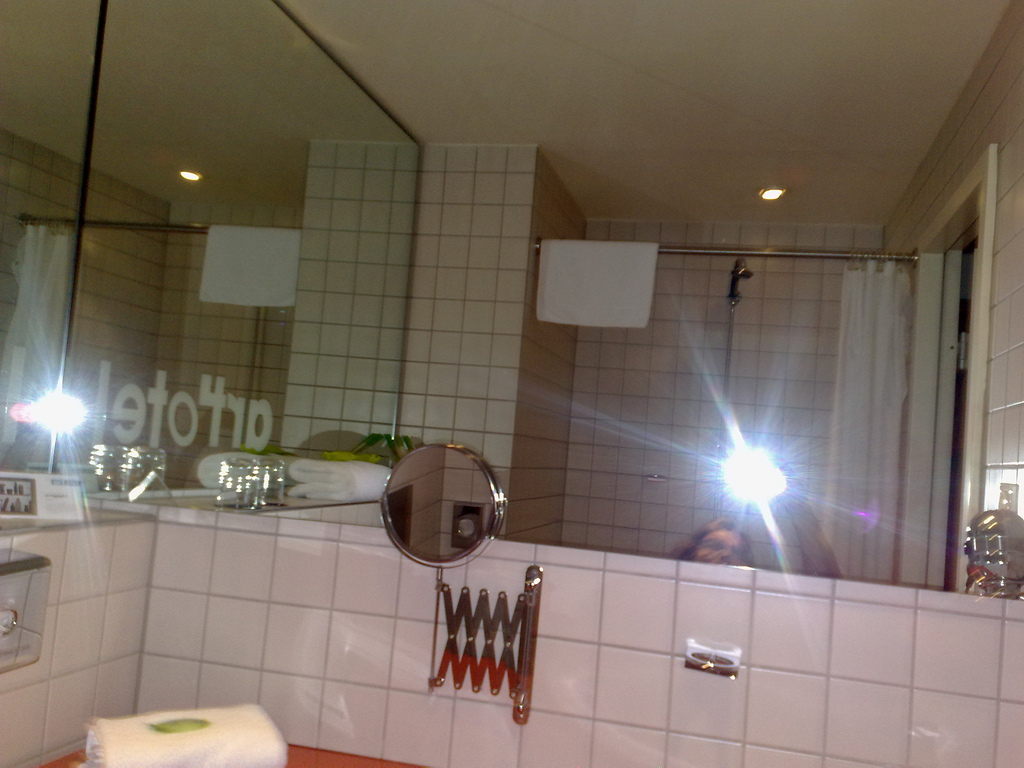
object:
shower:
[719, 259, 746, 305]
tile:
[247, 578, 344, 678]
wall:
[172, 519, 393, 738]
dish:
[678, 634, 748, 680]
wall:
[573, 553, 861, 764]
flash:
[557, 269, 908, 581]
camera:
[714, 430, 790, 510]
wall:
[154, 510, 852, 760]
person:
[675, 492, 844, 583]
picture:
[9, 7, 1017, 761]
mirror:
[56, 2, 420, 489]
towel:
[534, 234, 655, 329]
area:
[573, 214, 924, 564]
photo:
[9, 11, 1016, 759]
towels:
[79, 694, 282, 764]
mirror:
[380, 443, 507, 571]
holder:
[420, 565, 544, 723]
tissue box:
[0, 560, 51, 670]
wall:
[2, 513, 156, 763]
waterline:
[707, 310, 742, 471]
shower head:
[725, 263, 754, 276]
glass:
[215, 455, 251, 507]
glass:
[261, 455, 290, 508]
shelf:
[87, 484, 367, 532]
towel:
[187, 217, 304, 308]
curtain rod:
[531, 237, 921, 267]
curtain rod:
[0, 204, 209, 230]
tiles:
[194, 586, 266, 672]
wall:
[801, 582, 990, 765]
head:
[677, 523, 757, 567]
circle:
[751, 184, 779, 204]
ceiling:
[766, 53, 887, 168]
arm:
[780, 495, 850, 581]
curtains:
[833, 254, 937, 586]